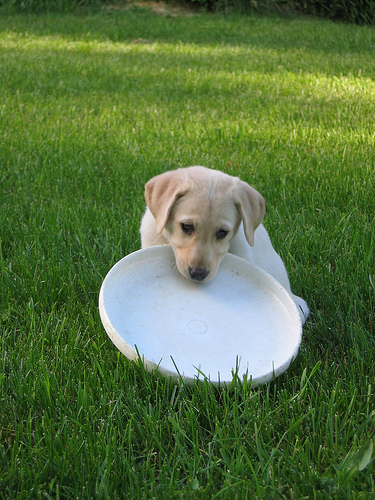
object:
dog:
[138, 162, 311, 331]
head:
[142, 164, 266, 286]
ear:
[143, 169, 189, 235]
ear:
[236, 176, 265, 251]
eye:
[180, 221, 194, 236]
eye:
[215, 227, 229, 241]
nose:
[187, 263, 210, 281]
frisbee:
[97, 242, 304, 396]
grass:
[0, 0, 374, 499]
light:
[0, 32, 374, 157]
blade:
[133, 342, 147, 379]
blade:
[168, 353, 186, 387]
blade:
[190, 363, 214, 389]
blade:
[216, 369, 222, 394]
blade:
[234, 353, 239, 395]